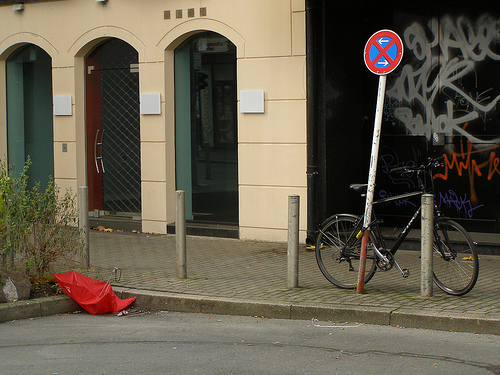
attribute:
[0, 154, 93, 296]
bush — green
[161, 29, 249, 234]
doorway — dark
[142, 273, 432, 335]
curb — concrete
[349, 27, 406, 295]
pole — tall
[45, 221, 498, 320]
sidewalk — gray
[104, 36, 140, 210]
mesh — silver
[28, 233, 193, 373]
umbrella — red, opened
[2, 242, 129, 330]
garbage — white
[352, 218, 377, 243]
lock — black, yellow 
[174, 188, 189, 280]
bollard — steel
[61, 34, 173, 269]
door — large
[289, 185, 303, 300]
post — concrete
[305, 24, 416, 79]
red sign — red and blue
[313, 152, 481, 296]
bicycle — black, parked 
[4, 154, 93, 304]
bushes — small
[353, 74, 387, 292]
pole — white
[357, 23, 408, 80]
sign — circular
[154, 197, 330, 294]
poles — short, silver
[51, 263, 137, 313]
umbrella — red, broken